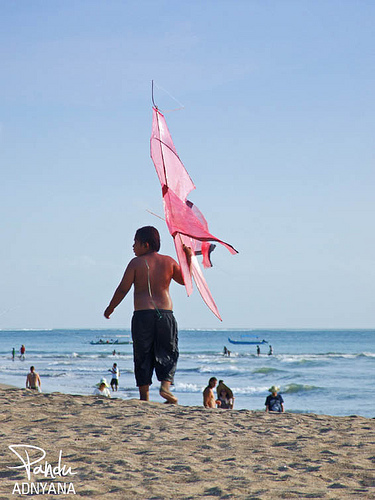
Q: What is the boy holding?
A: Kite.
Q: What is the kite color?
A: Pink.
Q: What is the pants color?
A: Black.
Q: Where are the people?
A: Beach.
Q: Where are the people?
A: Ocean.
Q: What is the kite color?
A: Pink.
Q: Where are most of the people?
A: In the water.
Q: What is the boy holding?
A: A kite.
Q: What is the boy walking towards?
A: The ocean.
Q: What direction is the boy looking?
A: Left.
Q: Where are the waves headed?
A: Towards the shore.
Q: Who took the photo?
A: Pandu Adnyana.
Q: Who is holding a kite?
A: The boy.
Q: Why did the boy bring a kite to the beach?
A: To fly it.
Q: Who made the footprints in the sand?
A: The people at the beach.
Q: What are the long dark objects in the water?
A: Boats.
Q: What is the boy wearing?
A: Shorts.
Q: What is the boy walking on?
A: Sand.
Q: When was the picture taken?
A: Daytime.